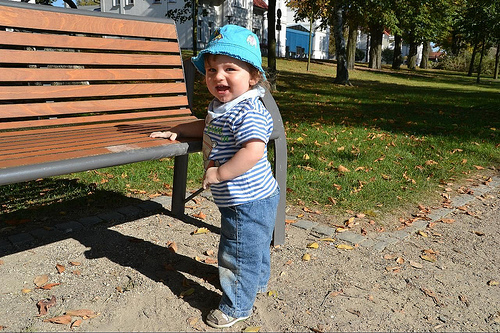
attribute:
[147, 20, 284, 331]
child — looking, smiling, little, small, white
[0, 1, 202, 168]
wood — wooden, brown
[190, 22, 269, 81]
child's hat — blue, small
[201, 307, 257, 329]
shoe — tiny, light brown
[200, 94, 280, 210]
shirt — striped, little, short sleeved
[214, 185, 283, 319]
jeans — tiny, blue, denim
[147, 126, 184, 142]
hand — tiny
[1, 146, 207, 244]
grass — green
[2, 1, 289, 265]
bench — brown, here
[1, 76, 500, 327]
leaves — dry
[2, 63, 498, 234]
leaves — dry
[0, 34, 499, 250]
grass — green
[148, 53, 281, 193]
skin — white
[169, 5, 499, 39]
leaves — green